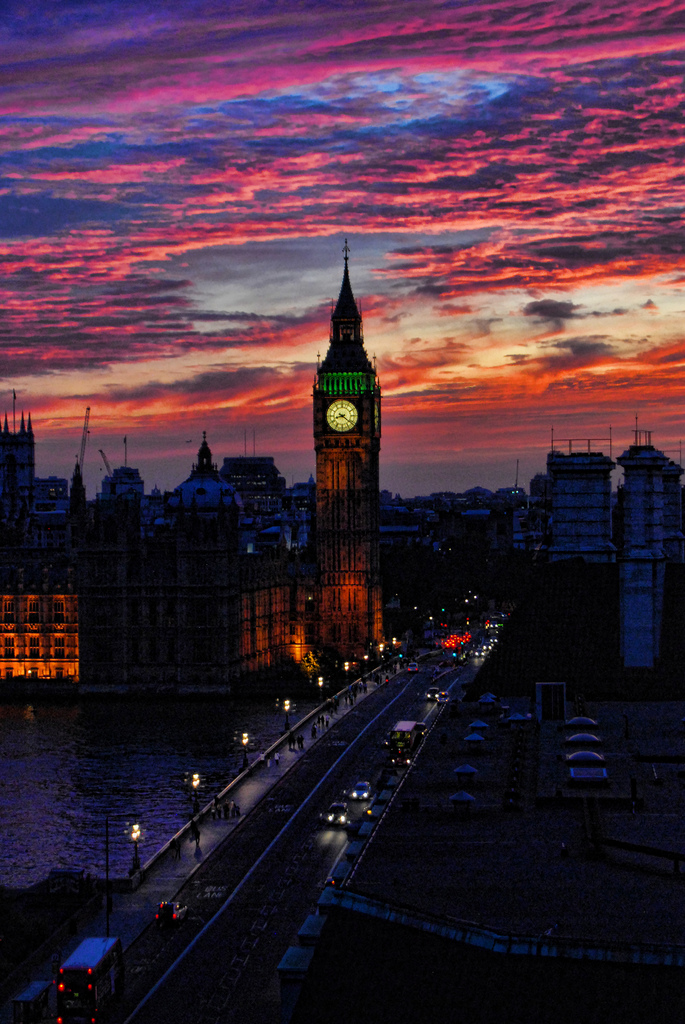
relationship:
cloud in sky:
[474, 279, 675, 341] [3, 0, 684, 493]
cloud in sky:
[30, 337, 320, 398] [3, 0, 684, 493]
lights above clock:
[319, 368, 367, 394] [326, 399, 360, 435]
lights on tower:
[319, 368, 367, 394] [308, 234, 387, 664]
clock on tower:
[326, 399, 360, 435] [308, 234, 387, 664]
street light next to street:
[128, 818, 145, 879] [1, 599, 515, 1022]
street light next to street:
[181, 768, 208, 821] [1, 599, 515, 1022]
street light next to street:
[233, 723, 257, 776] [1, 599, 515, 1022]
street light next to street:
[271, 694, 300, 730] [1, 599, 515, 1022]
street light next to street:
[307, 672, 333, 706] [1, 599, 515, 1022]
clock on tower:
[327, 395, 360, 436] [308, 234, 387, 664]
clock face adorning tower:
[323, 397, 359, 434] [308, 234, 387, 664]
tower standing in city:
[308, 234, 387, 664] [2, 235, 664, 697]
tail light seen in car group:
[443, 642, 450, 648] [438, 628, 472, 650]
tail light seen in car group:
[449, 642, 455, 646] [438, 628, 472, 650]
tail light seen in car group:
[463, 630, 470, 636] [438, 628, 472, 650]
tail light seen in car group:
[463, 635, 467, 641] [438, 628, 472, 650]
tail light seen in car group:
[447, 632, 454, 638] [438, 628, 472, 650]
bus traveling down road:
[54, 934, 127, 1022] [2, 599, 515, 1022]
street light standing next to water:
[127, 818, 144, 879] [4, 701, 316, 886]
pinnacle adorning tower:
[340, 235, 352, 259] [308, 234, 387, 664]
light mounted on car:
[153, 912, 160, 918] [150, 895, 188, 927]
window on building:
[44, 635, 68, 662] [0, 413, 83, 679]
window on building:
[44, 635, 68, 662] [0, 236, 407, 698]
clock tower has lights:
[308, 236, 390, 674] [315, 371, 381, 400]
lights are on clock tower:
[319, 369, 382, 401] [308, 236, 390, 674]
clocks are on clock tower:
[319, 393, 386, 450] [308, 236, 390, 674]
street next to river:
[44, 603, 508, 1015] [7, 694, 683, 972]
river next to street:
[3, 684, 320, 901] [44, 603, 508, 1015]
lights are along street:
[116, 593, 480, 845] [1, 599, 515, 1022]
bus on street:
[54, 934, 127, 1022] [44, 603, 508, 1015]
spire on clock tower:
[333, 219, 356, 289] [301, 227, 384, 671]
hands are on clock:
[337, 407, 359, 431] [320, 400, 367, 443]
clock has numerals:
[325, 395, 366, 452] [322, 402, 363, 438]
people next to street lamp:
[212, 785, 251, 836] [176, 769, 214, 871]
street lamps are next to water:
[112, 587, 488, 892] [0, 697, 320, 904]